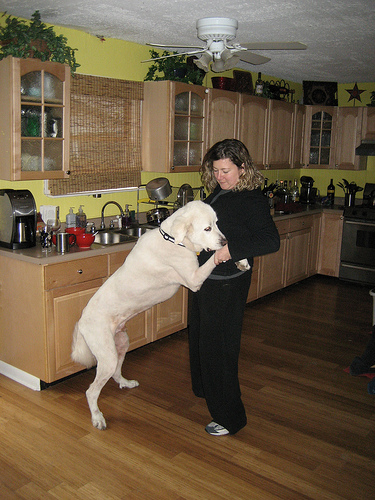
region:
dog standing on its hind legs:
[54, 255, 136, 408]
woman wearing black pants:
[200, 275, 264, 428]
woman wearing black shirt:
[202, 189, 280, 269]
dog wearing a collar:
[151, 221, 178, 249]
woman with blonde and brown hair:
[195, 143, 261, 191]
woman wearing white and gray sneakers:
[204, 408, 230, 440]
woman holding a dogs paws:
[197, 227, 260, 288]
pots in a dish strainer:
[135, 176, 174, 207]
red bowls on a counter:
[69, 217, 90, 248]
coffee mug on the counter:
[52, 227, 76, 252]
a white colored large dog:
[70, 200, 253, 430]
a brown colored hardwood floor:
[0, 273, 373, 498]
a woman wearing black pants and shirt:
[190, 138, 281, 437]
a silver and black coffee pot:
[2, 188, 35, 249]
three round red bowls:
[50, 225, 95, 249]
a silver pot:
[146, 174, 171, 209]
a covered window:
[44, 77, 143, 199]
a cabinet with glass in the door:
[0, 54, 71, 180]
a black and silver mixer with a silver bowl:
[298, 174, 318, 204]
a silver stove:
[337, 181, 373, 291]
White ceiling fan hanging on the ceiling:
[134, 14, 314, 77]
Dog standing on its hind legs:
[52, 193, 234, 446]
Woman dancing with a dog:
[67, 136, 280, 440]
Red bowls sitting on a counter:
[50, 221, 103, 256]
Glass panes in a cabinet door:
[17, 59, 67, 177]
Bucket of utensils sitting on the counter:
[337, 175, 364, 209]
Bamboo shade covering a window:
[46, 70, 146, 198]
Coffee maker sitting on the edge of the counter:
[0, 187, 38, 253]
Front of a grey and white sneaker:
[198, 416, 234, 437]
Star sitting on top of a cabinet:
[344, 78, 367, 107]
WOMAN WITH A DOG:
[68, 130, 292, 326]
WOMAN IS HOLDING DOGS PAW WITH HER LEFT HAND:
[158, 134, 293, 291]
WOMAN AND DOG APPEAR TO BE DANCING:
[72, 131, 291, 311]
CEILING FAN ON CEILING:
[134, 10, 311, 79]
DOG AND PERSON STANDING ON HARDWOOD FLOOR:
[27, 320, 357, 448]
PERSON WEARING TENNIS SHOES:
[167, 329, 268, 439]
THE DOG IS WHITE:
[66, 204, 223, 409]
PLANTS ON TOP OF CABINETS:
[2, 9, 197, 94]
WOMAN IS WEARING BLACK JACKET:
[178, 130, 280, 279]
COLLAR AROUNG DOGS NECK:
[148, 214, 224, 261]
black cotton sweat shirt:
[197, 186, 281, 274]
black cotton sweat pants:
[186, 263, 252, 429]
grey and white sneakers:
[205, 420, 228, 436]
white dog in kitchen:
[72, 198, 223, 427]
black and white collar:
[159, 225, 185, 248]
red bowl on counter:
[76, 232, 94, 248]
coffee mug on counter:
[58, 229, 76, 255]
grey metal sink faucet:
[99, 199, 124, 231]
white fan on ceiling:
[144, 17, 309, 71]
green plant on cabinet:
[1, 11, 82, 72]